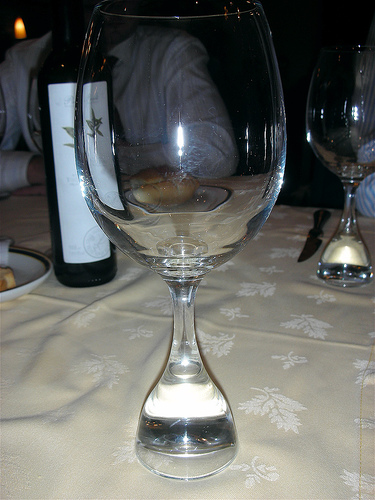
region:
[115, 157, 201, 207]
roll on a plate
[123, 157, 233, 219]
plate with roll on top of it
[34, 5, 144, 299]
bottle wine behind glass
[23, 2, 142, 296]
bottle of wine in front of person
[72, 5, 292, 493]
wine glass in front of wine bottle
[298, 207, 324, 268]
knife next to wine glass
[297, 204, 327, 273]
knife on the tablecloth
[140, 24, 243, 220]
left arm of man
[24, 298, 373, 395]
crease in the tablecloth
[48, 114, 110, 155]
picture on label of wine bottle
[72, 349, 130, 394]
A white flower design on the tablecloth.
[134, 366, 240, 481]
The base of a glass goblet.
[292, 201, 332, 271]
A small knife on the table.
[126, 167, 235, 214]
Bread reflected through the wine glass.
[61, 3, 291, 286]
Close up of a large wine glass.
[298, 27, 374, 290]
A wine glass adjacent to the knife on the table.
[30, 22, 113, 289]
A bottle of wine.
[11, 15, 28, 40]
A bright light in the background.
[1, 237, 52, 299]
A saucer containing a small piece of food.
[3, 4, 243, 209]
A man in the background staring at the table.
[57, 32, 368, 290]
The glass is clear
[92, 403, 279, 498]
The glass is on the table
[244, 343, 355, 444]
The table cloth is cream colored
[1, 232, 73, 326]
The plate is white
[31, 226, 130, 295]
The wine bottle is dark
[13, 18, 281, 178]
There is a person in the back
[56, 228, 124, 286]
The label on the wine bottle is white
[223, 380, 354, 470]
There are leaves on the table cloth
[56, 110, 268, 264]
The glass is empty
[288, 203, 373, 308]
There is a knife on the table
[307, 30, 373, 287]
a wine glass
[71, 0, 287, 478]
a large wine glass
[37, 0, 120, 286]
a bottle of red wine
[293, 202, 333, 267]
a metal table knife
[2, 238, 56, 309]
a plate with bread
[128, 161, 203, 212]
a large bread roll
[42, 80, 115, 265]
the label of a wine bottle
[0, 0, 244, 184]
a man sitting at a table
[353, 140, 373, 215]
a man's elbow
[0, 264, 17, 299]
a piece of bread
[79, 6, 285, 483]
a wine glass is on the table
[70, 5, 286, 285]
the bowl of the wine glass is empty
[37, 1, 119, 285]
a bottle of wine is on the table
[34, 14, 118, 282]
the bottle has a white label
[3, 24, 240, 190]
a man is behind the wine bottle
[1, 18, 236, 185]
the man is wearing a long sleeve white shirt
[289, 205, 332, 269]
a knife is on the table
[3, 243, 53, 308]
a plate with a cork is on the table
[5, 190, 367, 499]
the table has a cream tablecloth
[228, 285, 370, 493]
white embossed leaves are on the tablecloth